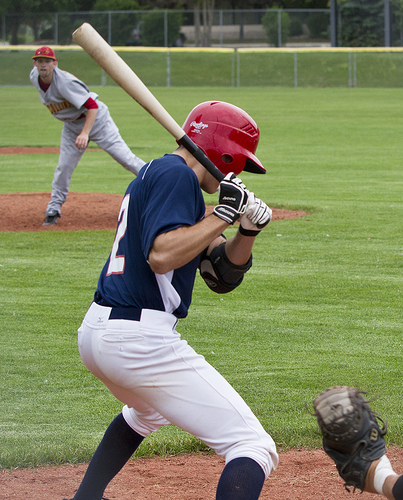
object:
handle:
[176, 129, 248, 207]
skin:
[161, 240, 196, 253]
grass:
[0, 260, 64, 437]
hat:
[31, 45, 57, 59]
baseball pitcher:
[26, 46, 156, 230]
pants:
[40, 110, 149, 212]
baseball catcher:
[315, 376, 403, 499]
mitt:
[314, 393, 389, 490]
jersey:
[94, 151, 209, 309]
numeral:
[104, 193, 131, 276]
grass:
[280, 245, 402, 385]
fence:
[0, 48, 403, 87]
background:
[18, 14, 383, 77]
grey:
[55, 85, 77, 95]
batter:
[78, 94, 277, 500]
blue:
[151, 177, 188, 207]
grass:
[274, 104, 396, 188]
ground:
[23, 468, 333, 493]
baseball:
[313, 385, 361, 433]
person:
[78, 99, 298, 500]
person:
[23, 46, 148, 228]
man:
[74, 101, 276, 500]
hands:
[215, 171, 248, 220]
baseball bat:
[70, 21, 226, 182]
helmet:
[179, 100, 265, 178]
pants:
[75, 301, 282, 474]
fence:
[0, 0, 400, 47]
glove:
[215, 169, 247, 223]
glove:
[240, 192, 273, 235]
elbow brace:
[198, 241, 254, 296]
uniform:
[28, 68, 148, 203]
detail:
[44, 98, 73, 115]